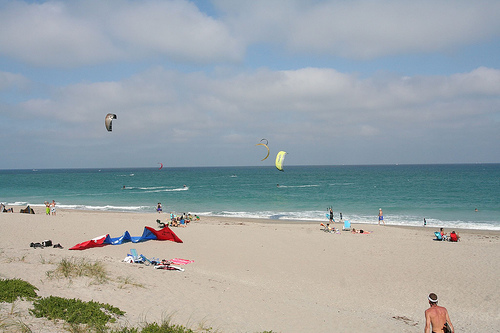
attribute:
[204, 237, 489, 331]
floor — light, brown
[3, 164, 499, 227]
water — light blue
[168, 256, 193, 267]
towel — pink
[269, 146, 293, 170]
kite — yellow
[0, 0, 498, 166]
clouds — thick, white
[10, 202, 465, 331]
floor — sandy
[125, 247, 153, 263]
chair — red, blue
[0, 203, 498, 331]
sand — light brown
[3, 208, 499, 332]
floor — covered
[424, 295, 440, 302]
band — white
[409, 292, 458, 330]
man — shirtless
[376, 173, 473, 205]
water — blue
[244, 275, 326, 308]
sand — brown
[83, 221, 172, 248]
tents — red, blue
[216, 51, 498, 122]
sky — blue, white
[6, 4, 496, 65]
clouds — white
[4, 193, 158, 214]
waves — small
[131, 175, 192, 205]
waves — white, few